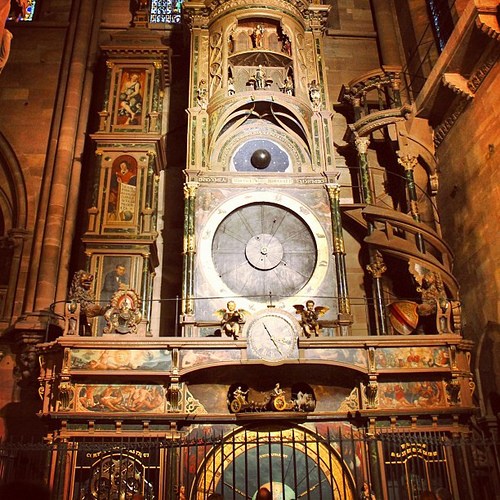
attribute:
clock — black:
[185, 159, 358, 333]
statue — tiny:
[239, 21, 275, 78]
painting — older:
[100, 150, 152, 237]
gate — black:
[60, 401, 477, 498]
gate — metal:
[16, 413, 490, 499]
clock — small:
[243, 308, 304, 361]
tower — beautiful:
[55, 13, 485, 498]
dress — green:
[124, 94, 134, 100]